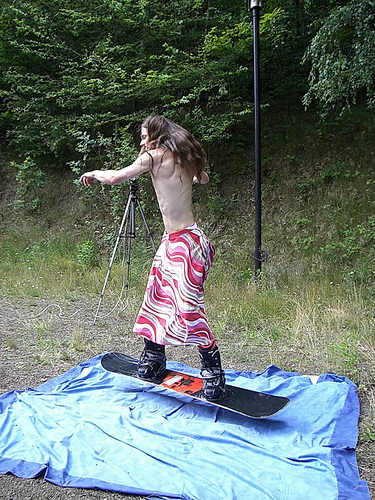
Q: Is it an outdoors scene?
A: Yes, it is outdoors.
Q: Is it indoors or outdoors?
A: It is outdoors.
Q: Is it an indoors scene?
A: No, it is outdoors.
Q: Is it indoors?
A: No, it is outdoors.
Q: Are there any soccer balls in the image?
A: No, there are no soccer balls.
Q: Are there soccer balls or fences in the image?
A: No, there are no soccer balls or fences.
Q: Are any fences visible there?
A: No, there are no fences.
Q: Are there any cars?
A: No, there are no cars.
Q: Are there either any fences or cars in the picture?
A: No, there are no cars or fences.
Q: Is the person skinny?
A: Yes, the person is skinny.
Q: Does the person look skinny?
A: Yes, the person is skinny.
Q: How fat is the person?
A: The person is skinny.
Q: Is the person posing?
A: Yes, the person is posing.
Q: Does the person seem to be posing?
A: Yes, the person is posing.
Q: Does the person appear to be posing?
A: Yes, the person is posing.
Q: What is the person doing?
A: The person is posing.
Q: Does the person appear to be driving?
A: No, the person is posing.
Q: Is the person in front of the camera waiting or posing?
A: The person is posing.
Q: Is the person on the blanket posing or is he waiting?
A: The person is posing.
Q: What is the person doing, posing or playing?
A: The person is posing.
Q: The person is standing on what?
A: The person is standing on the snowboard.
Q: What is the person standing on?
A: The person is standing on the snowboard.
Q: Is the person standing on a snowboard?
A: Yes, the person is standing on a snowboard.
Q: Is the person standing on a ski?
A: No, the person is standing on a snowboard.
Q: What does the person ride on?
A: The person rides on the snowboard.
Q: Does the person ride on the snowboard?
A: Yes, the person rides on the snowboard.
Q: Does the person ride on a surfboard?
A: No, the person rides on the snowboard.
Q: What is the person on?
A: The person is on the blanket.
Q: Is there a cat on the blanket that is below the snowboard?
A: No, there is a person on the blanket.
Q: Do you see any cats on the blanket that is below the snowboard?
A: No, there is a person on the blanket.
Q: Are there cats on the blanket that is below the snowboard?
A: No, there is a person on the blanket.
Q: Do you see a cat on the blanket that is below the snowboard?
A: No, there is a person on the blanket.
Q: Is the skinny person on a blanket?
A: Yes, the person is on a blanket.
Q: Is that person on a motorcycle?
A: No, the person is on a blanket.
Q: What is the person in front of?
A: The person is in front of the camera.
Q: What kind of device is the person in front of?
A: The person is in front of the camera.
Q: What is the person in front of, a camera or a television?
A: The person is in front of a camera.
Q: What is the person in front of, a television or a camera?
A: The person is in front of a camera.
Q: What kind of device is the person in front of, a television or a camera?
A: The person is in front of a camera.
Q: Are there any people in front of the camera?
A: Yes, there is a person in front of the camera.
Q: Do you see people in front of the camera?
A: Yes, there is a person in front of the camera.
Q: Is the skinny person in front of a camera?
A: Yes, the person is in front of a camera.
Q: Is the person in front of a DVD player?
A: No, the person is in front of a camera.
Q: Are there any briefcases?
A: No, there are no briefcases.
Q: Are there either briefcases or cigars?
A: No, there are no briefcases or cigars.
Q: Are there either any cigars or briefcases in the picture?
A: No, there are no briefcases or cigars.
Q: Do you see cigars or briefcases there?
A: No, there are no briefcases or cigars.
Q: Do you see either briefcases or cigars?
A: No, there are no briefcases or cigars.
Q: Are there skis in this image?
A: No, there are no skis.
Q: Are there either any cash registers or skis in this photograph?
A: No, there are no skis or cash registers.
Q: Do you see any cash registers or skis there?
A: No, there are no skis or cash registers.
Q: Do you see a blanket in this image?
A: Yes, there is a blanket.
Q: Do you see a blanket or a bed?
A: Yes, there is a blanket.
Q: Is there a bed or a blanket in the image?
A: Yes, there is a blanket.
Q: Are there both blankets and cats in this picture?
A: No, there is a blanket but no cats.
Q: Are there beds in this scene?
A: No, there are no beds.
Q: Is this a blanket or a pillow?
A: This is a blanket.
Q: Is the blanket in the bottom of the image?
A: Yes, the blanket is in the bottom of the image.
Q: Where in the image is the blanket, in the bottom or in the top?
A: The blanket is in the bottom of the image.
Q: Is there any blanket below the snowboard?
A: Yes, there is a blanket below the snowboard.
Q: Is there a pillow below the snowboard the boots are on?
A: No, there is a blanket below the snowboard.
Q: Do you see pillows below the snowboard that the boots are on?
A: No, there is a blanket below the snowboard.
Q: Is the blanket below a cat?
A: No, the blanket is below a snowboard.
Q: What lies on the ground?
A: The blanket lies on the ground.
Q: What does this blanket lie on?
A: The blanket lies on the ground.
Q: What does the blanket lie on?
A: The blanket lies on the ground.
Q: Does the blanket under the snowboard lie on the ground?
A: Yes, the blanket lies on the ground.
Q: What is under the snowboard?
A: The blanket is under the snowboard.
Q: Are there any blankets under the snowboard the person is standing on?
A: Yes, there is a blanket under the snowboard.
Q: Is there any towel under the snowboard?
A: No, there is a blanket under the snowboard.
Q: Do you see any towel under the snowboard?
A: No, there is a blanket under the snowboard.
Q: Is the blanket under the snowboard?
A: Yes, the blanket is under the snowboard.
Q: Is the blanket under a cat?
A: No, the blanket is under the snowboard.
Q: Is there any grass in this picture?
A: Yes, there is grass.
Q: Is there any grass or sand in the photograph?
A: Yes, there is grass.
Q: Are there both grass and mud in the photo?
A: No, there is grass but no mud.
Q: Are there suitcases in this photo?
A: No, there are no suitcases.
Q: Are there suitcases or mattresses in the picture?
A: No, there are no suitcases or mattresses.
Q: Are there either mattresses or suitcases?
A: No, there are no suitcases or mattresses.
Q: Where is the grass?
A: The grass is on the ground.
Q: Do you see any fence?
A: No, there are no fences.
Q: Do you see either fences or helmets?
A: No, there are no fences or helmets.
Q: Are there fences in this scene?
A: No, there are no fences.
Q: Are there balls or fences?
A: No, there are no fences or balls.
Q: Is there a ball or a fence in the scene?
A: No, there are no fences or balls.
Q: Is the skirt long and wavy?
A: Yes, the skirt is long and wavy.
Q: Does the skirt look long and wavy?
A: Yes, the skirt is long and wavy.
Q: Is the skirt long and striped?
A: Yes, the skirt is long and striped.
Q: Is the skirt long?
A: Yes, the skirt is long.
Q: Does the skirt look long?
A: Yes, the skirt is long.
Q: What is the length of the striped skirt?
A: The skirt is long.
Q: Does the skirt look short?
A: No, the skirt is long.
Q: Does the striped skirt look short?
A: No, the skirt is long.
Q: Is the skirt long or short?
A: The skirt is long.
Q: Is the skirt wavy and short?
A: No, the skirt is wavy but long.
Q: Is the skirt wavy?
A: Yes, the skirt is wavy.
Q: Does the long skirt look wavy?
A: Yes, the skirt is wavy.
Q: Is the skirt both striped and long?
A: Yes, the skirt is striped and long.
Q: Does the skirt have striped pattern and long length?
A: Yes, the skirt is striped and long.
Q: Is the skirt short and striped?
A: No, the skirt is striped but long.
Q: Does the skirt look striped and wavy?
A: Yes, the skirt is striped and wavy.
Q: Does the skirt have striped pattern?
A: Yes, the skirt is striped.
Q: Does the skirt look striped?
A: Yes, the skirt is striped.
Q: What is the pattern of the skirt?
A: The skirt is striped.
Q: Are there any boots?
A: Yes, there are boots.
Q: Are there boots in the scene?
A: Yes, there are boots.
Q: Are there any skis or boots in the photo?
A: Yes, there are boots.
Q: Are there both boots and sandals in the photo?
A: No, there are boots but no sandals.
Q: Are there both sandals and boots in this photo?
A: No, there are boots but no sandals.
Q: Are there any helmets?
A: No, there are no helmets.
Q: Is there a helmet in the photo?
A: No, there are no helmets.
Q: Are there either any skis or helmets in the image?
A: No, there are no helmets or skis.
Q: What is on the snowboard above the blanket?
A: The boots are on the snowboard.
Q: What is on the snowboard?
A: The boots are on the snowboard.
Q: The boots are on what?
A: The boots are on the snow board.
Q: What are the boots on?
A: The boots are on the snow board.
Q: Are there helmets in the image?
A: No, there are no helmets.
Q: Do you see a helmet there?
A: No, there are no helmets.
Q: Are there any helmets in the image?
A: No, there are no helmets.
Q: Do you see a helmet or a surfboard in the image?
A: No, there are no helmets or surfboards.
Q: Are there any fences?
A: No, there are no fences.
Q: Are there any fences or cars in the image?
A: No, there are no fences or cars.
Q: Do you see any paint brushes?
A: No, there are no paint brushes.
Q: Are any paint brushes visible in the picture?
A: No, there are no paint brushes.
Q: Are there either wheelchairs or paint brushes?
A: No, there are no paint brushes or wheelchairs.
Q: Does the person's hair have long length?
A: Yes, the hair is long.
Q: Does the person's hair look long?
A: Yes, the hair is long.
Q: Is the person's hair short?
A: No, the hair is long.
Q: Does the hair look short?
A: No, the hair is long.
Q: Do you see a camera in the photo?
A: Yes, there is a camera.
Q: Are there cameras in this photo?
A: Yes, there is a camera.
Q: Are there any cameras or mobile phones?
A: Yes, there is a camera.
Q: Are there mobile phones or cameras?
A: Yes, there is a camera.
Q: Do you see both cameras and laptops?
A: No, there is a camera but no laptops.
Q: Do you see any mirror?
A: No, there are no mirrors.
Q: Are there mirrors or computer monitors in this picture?
A: No, there are no mirrors or computer monitors.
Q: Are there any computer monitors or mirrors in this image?
A: No, there are no mirrors or computer monitors.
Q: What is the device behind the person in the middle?
A: The device is a camera.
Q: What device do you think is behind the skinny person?
A: The device is a camera.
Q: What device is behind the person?
A: The device is a camera.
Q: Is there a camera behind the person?
A: Yes, there is a camera behind the person.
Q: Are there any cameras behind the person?
A: Yes, there is a camera behind the person.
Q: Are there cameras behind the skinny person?
A: Yes, there is a camera behind the person.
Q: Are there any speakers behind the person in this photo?
A: No, there is a camera behind the person.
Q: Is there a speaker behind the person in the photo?
A: No, there is a camera behind the person.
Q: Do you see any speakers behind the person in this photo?
A: No, there is a camera behind the person.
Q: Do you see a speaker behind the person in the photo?
A: No, there is a camera behind the person.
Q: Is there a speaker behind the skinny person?
A: No, there is a camera behind the person.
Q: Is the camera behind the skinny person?
A: Yes, the camera is behind the person.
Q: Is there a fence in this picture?
A: No, there are no fences.